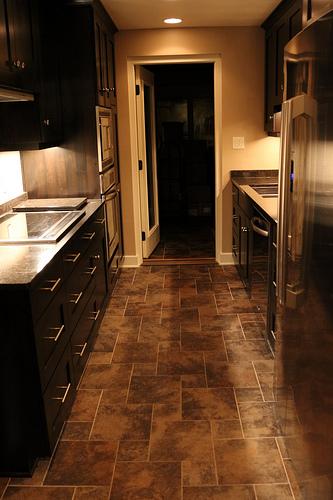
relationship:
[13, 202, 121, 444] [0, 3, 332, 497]
drawers are in kitchen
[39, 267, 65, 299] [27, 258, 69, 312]
handle on drawer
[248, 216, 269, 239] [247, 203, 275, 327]
handle on appliance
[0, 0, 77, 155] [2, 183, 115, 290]
cabinets over counter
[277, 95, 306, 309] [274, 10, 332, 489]
handle on refrigerator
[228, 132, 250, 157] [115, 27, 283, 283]
power square on wall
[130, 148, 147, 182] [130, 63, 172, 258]
hinge on door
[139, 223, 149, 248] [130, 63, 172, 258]
lower hinge on door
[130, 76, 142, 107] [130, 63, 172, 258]
upper hinge on door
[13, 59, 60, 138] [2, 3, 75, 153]
handles are on cabinets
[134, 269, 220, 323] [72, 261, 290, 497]
tiles are on floor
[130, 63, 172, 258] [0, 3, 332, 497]
door in kitchen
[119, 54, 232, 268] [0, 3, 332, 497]
doorway in kitchen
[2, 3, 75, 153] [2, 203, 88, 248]
cabinets are over range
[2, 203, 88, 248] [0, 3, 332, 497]
range in kitchen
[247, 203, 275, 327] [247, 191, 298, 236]
appliance under counter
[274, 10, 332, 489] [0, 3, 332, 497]
refrigerator in kitchen